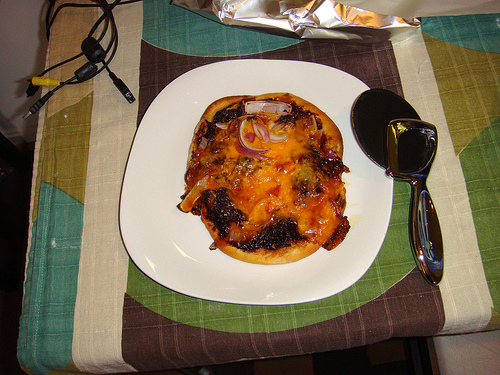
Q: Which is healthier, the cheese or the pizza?
A: The cheese is healthier than the pizza.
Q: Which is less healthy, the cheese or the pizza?
A: The pizza is less healthy than the cheese.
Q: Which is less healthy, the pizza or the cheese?
A: The pizza is less healthy than the cheese.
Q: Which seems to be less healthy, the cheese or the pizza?
A: The pizza is less healthy than the cheese.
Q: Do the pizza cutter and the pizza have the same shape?
A: Yes, both the pizza cutter and the pizza are round.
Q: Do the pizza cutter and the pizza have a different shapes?
A: No, both the pizza cutter and the pizza are round.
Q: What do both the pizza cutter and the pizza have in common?
A: The shape, both the pizza cutter and the pizza are round.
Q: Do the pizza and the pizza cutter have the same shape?
A: Yes, both the pizza and the pizza cutter are round.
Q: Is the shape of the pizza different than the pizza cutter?
A: No, both the pizza and the pizza cutter are round.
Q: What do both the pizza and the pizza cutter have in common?
A: The shape, both the pizza and the pizza cutter are round.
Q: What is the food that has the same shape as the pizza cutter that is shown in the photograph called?
A: The food is a pizza.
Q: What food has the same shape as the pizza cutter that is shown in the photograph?
A: The pizza is the same shape as the pizza cutter.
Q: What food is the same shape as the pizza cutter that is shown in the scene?
A: The pizza is the same shape as the pizza cutter.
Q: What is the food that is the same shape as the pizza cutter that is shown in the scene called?
A: The food is a pizza.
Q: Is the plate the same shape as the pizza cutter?
A: No, the pizza cutter is round and the plate is square.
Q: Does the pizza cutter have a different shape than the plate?
A: Yes, the pizza cutter is round and the plate is square.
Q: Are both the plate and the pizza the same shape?
A: No, the pizza is round and the plate is square.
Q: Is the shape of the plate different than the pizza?
A: Yes, the pizza is round and the plate is square.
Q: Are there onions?
A: Yes, there are onions.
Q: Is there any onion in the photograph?
A: Yes, there are onions.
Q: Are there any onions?
A: Yes, there are onions.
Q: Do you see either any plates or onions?
A: Yes, there are onions.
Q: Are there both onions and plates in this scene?
A: Yes, there are both onions and a plate.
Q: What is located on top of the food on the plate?
A: The onions are on top of the pizza.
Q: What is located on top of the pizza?
A: The onions are on top of the pizza.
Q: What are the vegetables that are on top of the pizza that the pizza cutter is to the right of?
A: The vegetables are onions.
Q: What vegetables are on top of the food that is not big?
A: The vegetables are onions.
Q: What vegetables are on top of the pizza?
A: The vegetables are onions.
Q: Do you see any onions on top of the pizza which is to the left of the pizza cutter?
A: Yes, there are onions on top of the pizza.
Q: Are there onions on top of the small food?
A: Yes, there are onions on top of the pizza.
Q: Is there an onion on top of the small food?
A: Yes, there are onions on top of the pizza.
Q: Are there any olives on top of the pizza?
A: No, there are onions on top of the pizza.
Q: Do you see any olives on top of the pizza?
A: No, there are onions on top of the pizza.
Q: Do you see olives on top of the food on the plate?
A: No, there are onions on top of the pizza.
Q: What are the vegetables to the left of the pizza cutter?
A: The vegetables are onions.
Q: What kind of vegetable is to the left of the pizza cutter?
A: The vegetables are onions.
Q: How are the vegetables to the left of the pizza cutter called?
A: The vegetables are onions.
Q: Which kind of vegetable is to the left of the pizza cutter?
A: The vegetables are onions.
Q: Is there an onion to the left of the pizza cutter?
A: Yes, there are onions to the left of the pizza cutter.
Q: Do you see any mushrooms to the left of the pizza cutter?
A: No, there are onions to the left of the pizza cutter.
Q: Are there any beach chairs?
A: No, there are no beach chairs.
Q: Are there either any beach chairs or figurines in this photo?
A: No, there are no beach chairs or figurines.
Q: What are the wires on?
A: The wires are on the table.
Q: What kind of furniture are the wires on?
A: The wires are on the table.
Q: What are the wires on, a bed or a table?
A: The wires are on a table.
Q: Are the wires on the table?
A: Yes, the wires are on the table.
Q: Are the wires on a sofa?
A: No, the wires are on the table.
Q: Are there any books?
A: No, there are no books.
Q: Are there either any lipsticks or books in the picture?
A: No, there are no books or lipsticks.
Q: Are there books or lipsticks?
A: No, there are no books or lipsticks.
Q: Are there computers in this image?
A: No, there are no computers.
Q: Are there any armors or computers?
A: No, there are no computers or armors.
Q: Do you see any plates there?
A: Yes, there is a plate.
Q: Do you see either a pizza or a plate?
A: Yes, there is a plate.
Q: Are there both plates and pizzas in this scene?
A: Yes, there are both a plate and a pizza.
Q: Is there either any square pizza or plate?
A: Yes, there is a square plate.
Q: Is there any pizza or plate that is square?
A: Yes, the plate is square.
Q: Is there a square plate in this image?
A: Yes, there is a square plate.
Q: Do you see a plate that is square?
A: Yes, there is a plate that is square.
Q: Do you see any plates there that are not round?
A: Yes, there is a square plate.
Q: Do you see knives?
A: No, there are no knives.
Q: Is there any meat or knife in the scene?
A: No, there are no knives or meat.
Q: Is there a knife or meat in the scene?
A: No, there are no knives or meat.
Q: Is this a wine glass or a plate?
A: This is a plate.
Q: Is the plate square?
A: Yes, the plate is square.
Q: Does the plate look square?
A: Yes, the plate is square.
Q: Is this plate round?
A: No, the plate is square.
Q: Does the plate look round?
A: No, the plate is square.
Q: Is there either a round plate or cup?
A: No, there is a plate but it is square.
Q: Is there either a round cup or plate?
A: No, there is a plate but it is square.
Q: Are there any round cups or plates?
A: No, there is a plate but it is square.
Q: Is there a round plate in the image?
A: No, there is a plate but it is square.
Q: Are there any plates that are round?
A: No, there is a plate but it is square.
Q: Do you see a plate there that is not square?
A: No, there is a plate but it is square.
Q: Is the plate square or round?
A: The plate is square.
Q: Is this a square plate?
A: Yes, this is a square plate.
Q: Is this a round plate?
A: No, this is a square plate.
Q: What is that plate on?
A: The plate is on the table.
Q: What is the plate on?
A: The plate is on the table.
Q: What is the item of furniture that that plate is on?
A: The piece of furniture is a table.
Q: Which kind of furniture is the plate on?
A: The plate is on the table.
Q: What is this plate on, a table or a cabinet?
A: The plate is on a table.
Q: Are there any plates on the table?
A: Yes, there is a plate on the table.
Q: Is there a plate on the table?
A: Yes, there is a plate on the table.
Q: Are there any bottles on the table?
A: No, there is a plate on the table.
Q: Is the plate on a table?
A: Yes, the plate is on a table.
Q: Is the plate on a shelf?
A: No, the plate is on a table.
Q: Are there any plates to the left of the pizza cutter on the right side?
A: Yes, there is a plate to the left of the pizza cutter.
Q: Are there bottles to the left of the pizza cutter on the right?
A: No, there is a plate to the left of the pizza cutter.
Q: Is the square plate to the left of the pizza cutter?
A: Yes, the plate is to the left of the pizza cutter.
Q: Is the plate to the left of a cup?
A: No, the plate is to the left of the pizza cutter.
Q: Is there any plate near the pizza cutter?
A: Yes, there is a plate near the pizza cutter.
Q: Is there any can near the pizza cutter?
A: No, there is a plate near the pizza cutter.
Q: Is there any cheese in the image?
A: Yes, there is cheese.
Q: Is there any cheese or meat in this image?
A: Yes, there is cheese.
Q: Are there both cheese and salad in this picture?
A: No, there is cheese but no salad.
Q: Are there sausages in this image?
A: No, there are no sausages.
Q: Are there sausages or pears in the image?
A: No, there are no sausages or pears.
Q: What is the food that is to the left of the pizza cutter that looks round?
A: The food is cheese.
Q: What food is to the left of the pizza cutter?
A: The food is cheese.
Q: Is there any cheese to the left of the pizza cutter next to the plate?
A: Yes, there is cheese to the left of the pizza cutter.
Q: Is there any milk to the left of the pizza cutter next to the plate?
A: No, there is cheese to the left of the pizza cutter.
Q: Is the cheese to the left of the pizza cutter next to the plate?
A: Yes, the cheese is to the left of the pizza cutter.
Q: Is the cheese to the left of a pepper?
A: No, the cheese is to the left of the pizza cutter.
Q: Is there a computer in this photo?
A: No, there are no computers.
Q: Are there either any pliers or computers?
A: No, there are no computers or pliers.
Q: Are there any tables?
A: Yes, there is a table.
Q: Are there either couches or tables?
A: Yes, there is a table.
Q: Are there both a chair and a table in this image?
A: No, there is a table but no chairs.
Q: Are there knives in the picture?
A: No, there are no knives.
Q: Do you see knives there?
A: No, there are no knives.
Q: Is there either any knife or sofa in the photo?
A: No, there are no knives or sofas.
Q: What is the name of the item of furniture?
A: The piece of furniture is a table.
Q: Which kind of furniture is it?
A: The piece of furniture is a table.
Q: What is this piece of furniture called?
A: This is a table.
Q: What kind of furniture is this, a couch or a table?
A: This is a table.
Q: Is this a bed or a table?
A: This is a table.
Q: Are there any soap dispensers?
A: No, there are no soap dispensers.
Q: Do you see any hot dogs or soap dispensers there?
A: No, there are no soap dispensers or hot dogs.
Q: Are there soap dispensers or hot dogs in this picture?
A: No, there are no soap dispensers or hot dogs.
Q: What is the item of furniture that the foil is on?
A: The piece of furniture is a table.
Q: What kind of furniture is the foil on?
A: The foil is on the table.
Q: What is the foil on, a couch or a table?
A: The foil is on a table.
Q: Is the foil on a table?
A: Yes, the foil is on a table.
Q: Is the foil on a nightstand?
A: No, the foil is on a table.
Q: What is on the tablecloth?
A: The foil is on the tablecloth.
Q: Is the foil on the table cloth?
A: Yes, the foil is on the table cloth.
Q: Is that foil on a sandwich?
A: No, the foil is on the table cloth.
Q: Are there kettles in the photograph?
A: No, there are no kettles.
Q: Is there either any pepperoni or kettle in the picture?
A: No, there are no kettles or pepperoni.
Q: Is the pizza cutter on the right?
A: Yes, the pizza cutter is on the right of the image.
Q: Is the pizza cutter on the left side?
A: No, the pizza cutter is on the right of the image.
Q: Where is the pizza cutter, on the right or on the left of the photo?
A: The pizza cutter is on the right of the image.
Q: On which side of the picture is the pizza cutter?
A: The pizza cutter is on the right of the image.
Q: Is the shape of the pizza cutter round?
A: Yes, the pizza cutter is round.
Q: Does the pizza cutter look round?
A: Yes, the pizza cutter is round.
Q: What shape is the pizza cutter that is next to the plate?
A: The pizza cutter is round.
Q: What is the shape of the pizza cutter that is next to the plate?
A: The pizza cutter is round.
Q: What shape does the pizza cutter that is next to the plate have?
A: The pizza cutter has round shape.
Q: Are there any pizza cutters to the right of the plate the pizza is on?
A: Yes, there is a pizza cutter to the right of the plate.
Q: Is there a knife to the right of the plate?
A: No, there is a pizza cutter to the right of the plate.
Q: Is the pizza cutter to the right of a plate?
A: Yes, the pizza cutter is to the right of a plate.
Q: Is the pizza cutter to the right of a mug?
A: No, the pizza cutter is to the right of a plate.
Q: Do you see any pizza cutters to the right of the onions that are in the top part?
A: Yes, there is a pizza cutter to the right of the onions.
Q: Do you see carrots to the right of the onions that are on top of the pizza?
A: No, there is a pizza cutter to the right of the onions.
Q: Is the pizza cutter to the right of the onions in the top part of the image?
A: Yes, the pizza cutter is to the right of the onions.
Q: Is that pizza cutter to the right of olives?
A: No, the pizza cutter is to the right of the onions.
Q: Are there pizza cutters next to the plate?
A: Yes, there is a pizza cutter next to the plate.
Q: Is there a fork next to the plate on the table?
A: No, there is a pizza cutter next to the plate.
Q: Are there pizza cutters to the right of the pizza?
A: Yes, there is a pizza cutter to the right of the pizza.